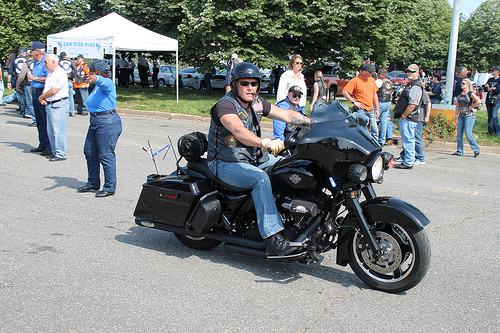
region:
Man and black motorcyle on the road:
[127, 60, 437, 295]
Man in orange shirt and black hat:
[337, 60, 382, 155]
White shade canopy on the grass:
[40, 5, 180, 105]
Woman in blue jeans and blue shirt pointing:
[71, 55, 121, 200]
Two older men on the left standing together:
[20, 35, 67, 160]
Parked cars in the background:
[121, 57, 426, 102]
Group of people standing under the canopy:
[110, 46, 175, 91]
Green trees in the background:
[0, 0, 496, 96]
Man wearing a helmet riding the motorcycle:
[202, 60, 307, 261]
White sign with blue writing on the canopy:
[43, 32, 116, 64]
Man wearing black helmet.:
[224, 60, 285, 114]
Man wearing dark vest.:
[214, 103, 284, 162]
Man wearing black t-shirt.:
[201, 100, 262, 151]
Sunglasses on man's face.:
[234, 76, 272, 96]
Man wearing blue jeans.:
[215, 143, 287, 219]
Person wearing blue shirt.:
[86, 78, 143, 120]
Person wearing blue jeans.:
[76, 130, 142, 185]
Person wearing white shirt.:
[36, 86, 82, 98]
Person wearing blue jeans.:
[43, 113, 83, 150]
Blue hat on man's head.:
[26, 40, 61, 70]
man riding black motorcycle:
[131, 55, 433, 297]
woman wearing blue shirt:
[71, 57, 127, 201]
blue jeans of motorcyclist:
[204, 153, 291, 238]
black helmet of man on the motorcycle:
[231, 55, 258, 96]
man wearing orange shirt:
[340, 57, 385, 150]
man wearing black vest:
[395, 65, 422, 170]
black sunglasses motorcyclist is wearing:
[236, 77, 258, 92]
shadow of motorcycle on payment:
[120, 218, 300, 290]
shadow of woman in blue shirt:
[45, 167, 76, 192]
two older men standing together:
[18, 39, 72, 161]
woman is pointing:
[73, 56, 125, 203]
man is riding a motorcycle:
[131, 58, 433, 295]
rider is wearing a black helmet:
[201, 55, 314, 265]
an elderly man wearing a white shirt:
[37, 52, 73, 166]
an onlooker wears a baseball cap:
[387, 59, 424, 172]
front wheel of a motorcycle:
[331, 192, 433, 292]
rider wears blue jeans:
[202, 60, 310, 258]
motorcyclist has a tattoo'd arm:
[267, 103, 314, 129]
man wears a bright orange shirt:
[340, 60, 380, 152]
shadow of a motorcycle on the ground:
[103, 218, 408, 303]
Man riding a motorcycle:
[130, 63, 432, 293]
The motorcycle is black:
[134, 97, 429, 294]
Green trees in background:
[1, 1, 498, 74]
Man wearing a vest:
[208, 95, 268, 162]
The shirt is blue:
[85, 75, 116, 110]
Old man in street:
[38, 53, 67, 160]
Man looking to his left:
[394, 64, 421, 169]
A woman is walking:
[453, 79, 479, 158]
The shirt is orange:
[346, 74, 378, 106]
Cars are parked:
[132, 61, 272, 92]